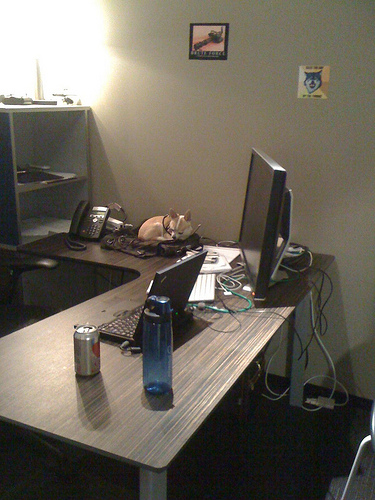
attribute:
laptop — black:
[76, 240, 213, 357]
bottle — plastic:
[140, 294, 172, 394]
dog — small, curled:
[138, 207, 195, 241]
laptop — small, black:
[90, 246, 207, 349]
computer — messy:
[158, 144, 304, 309]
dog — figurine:
[132, 207, 194, 248]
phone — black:
[56, 197, 111, 253]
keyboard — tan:
[304, 395, 334, 407]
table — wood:
[0, 214, 329, 497]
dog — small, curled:
[136, 206, 193, 246]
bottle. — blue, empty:
[117, 280, 198, 416]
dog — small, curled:
[134, 210, 195, 245]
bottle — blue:
[139, 291, 184, 392]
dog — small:
[132, 202, 195, 243]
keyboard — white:
[191, 274, 219, 305]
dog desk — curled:
[205, 214, 218, 259]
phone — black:
[64, 200, 115, 253]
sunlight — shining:
[3, 4, 103, 94]